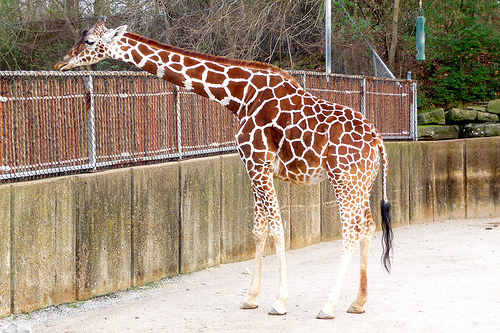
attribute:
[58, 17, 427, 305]
spot — brown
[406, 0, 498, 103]
leaves — green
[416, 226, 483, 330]
groundsurface — light brown, dirt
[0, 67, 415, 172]
fence — metal, chain link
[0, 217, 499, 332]
ground — dirt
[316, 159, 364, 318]
leg — rear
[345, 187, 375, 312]
leg — rear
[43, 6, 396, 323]
giraffe — tall, brown, white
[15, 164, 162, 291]
wall — brown, concrete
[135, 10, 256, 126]
neck — long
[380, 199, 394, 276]
tail hair — black